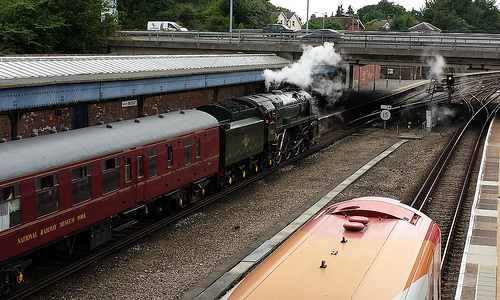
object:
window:
[195, 137, 202, 159]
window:
[167, 145, 175, 168]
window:
[136, 153, 147, 179]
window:
[124, 157, 134, 185]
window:
[34, 171, 62, 220]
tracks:
[411, 179, 429, 204]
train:
[0, 76, 326, 299]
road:
[113, 30, 499, 48]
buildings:
[407, 20, 443, 34]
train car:
[0, 106, 223, 294]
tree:
[418, 0, 499, 32]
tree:
[219, 0, 295, 32]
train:
[215, 193, 445, 300]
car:
[0, 107, 223, 294]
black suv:
[262, 24, 301, 38]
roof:
[0, 53, 294, 85]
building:
[0, 52, 298, 144]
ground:
[0, 76, 500, 299]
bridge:
[105, 28, 500, 60]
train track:
[5, 125, 362, 300]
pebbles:
[118, 276, 125, 279]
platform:
[453, 117, 500, 300]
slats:
[339, 173, 364, 185]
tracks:
[448, 208, 458, 241]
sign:
[379, 105, 391, 121]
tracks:
[474, 122, 488, 153]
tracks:
[406, 168, 435, 204]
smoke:
[260, 40, 350, 107]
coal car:
[195, 94, 267, 169]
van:
[146, 20, 189, 32]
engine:
[237, 77, 320, 164]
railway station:
[0, 31, 500, 300]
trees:
[173, 2, 181, 11]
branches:
[14, 5, 28, 8]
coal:
[208, 99, 251, 112]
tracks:
[460, 172, 472, 192]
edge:
[453, 117, 497, 296]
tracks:
[402, 99, 427, 107]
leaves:
[39, 20, 45, 23]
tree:
[0, 0, 126, 56]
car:
[301, 28, 345, 40]